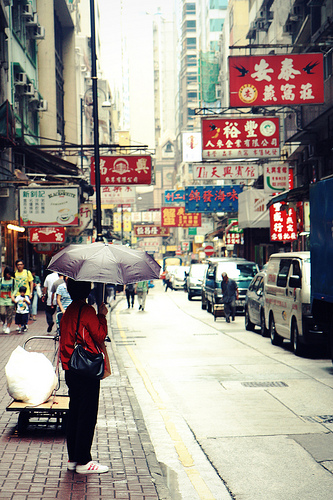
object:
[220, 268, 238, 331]
man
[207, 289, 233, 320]
cart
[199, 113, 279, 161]
sign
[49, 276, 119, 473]
woman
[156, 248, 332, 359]
cars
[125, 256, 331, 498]
street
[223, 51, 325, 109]
sign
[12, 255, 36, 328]
person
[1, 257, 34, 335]
family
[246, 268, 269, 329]
car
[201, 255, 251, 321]
van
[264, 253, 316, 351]
van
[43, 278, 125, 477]
person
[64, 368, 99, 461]
pants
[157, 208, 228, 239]
signs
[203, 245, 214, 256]
street sign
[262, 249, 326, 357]
van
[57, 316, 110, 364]
coat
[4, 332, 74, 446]
cart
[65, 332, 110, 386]
bag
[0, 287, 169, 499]
sidewalk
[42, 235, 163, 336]
umbrella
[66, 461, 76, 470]
shoe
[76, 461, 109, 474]
shoe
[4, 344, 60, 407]
bag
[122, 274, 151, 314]
people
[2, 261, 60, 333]
people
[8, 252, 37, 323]
man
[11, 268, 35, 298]
yellow shirt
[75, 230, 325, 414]
road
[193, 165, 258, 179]
sign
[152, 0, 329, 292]
building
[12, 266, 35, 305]
shirt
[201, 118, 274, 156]
chinese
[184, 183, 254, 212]
sign